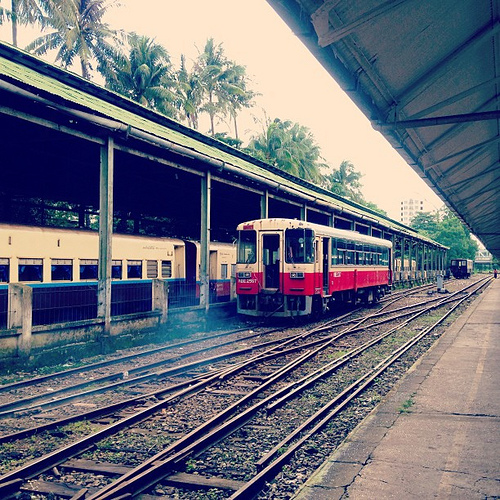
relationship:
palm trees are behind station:
[1, 1, 384, 217] [3, 1, 500, 500]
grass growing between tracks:
[3, 299, 454, 498] [2, 271, 493, 500]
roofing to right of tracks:
[268, 1, 496, 263] [2, 271, 493, 500]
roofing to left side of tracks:
[1, 36, 452, 258] [2, 271, 493, 500]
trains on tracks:
[236, 214, 397, 324] [2, 271, 493, 500]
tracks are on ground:
[2, 271, 493, 500] [2, 271, 493, 500]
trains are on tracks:
[450, 254, 477, 281] [2, 271, 493, 500]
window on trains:
[234, 225, 261, 266] [236, 214, 397, 324]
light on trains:
[285, 269, 309, 281] [236, 214, 397, 324]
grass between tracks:
[3, 299, 454, 498] [2, 271, 493, 500]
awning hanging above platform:
[268, 1, 496, 263] [277, 273, 498, 500]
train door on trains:
[258, 227, 283, 290] [236, 214, 397, 324]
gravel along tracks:
[2, 274, 488, 500] [2, 271, 493, 500]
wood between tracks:
[1, 268, 487, 500] [2, 271, 493, 500]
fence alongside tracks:
[2, 274, 239, 359] [2, 271, 493, 500]